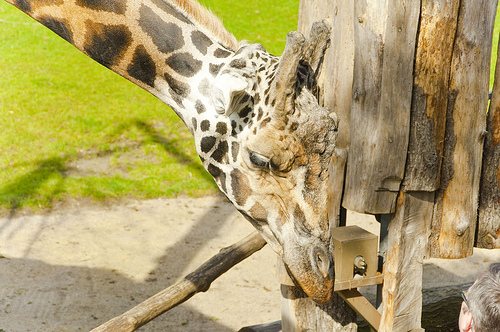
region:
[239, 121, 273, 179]
A giraffe's eye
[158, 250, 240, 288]
A wooden bar in the photo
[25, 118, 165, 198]
Grass on the ground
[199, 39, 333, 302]
A giraffe's neck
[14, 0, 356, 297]
A giraffe in the photo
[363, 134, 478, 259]
Wooden bars in the photo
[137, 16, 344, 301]
A giraffe eating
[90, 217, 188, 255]
A bare ground in the photo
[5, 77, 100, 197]
Grass in the photo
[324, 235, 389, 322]
Metal bar in the photo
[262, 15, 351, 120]
Giraffe ears pointing up.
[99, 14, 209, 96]
Spots on the giraffe's neck.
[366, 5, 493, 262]
Wooden fence beside giraffe's head.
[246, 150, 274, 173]
The eye of a giraffe.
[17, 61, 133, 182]
Grass field in the background.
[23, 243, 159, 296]
Sandy area near the grass.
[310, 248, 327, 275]
Small giraffe nostril.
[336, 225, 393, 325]
Metal bar securing wood.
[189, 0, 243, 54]
Giraffe mane on it's neck.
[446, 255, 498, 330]
Person watching the giraffe.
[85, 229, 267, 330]
A stick under a giraffes mouth.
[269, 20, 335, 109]
Tan horns on top of a giraffes head.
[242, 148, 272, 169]
Dark eye on a giraffes face.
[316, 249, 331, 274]
Nostril on a giraffes face.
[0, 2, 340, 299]
Brown and white giraffe.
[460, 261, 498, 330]
The brown haired head of a man in glasses.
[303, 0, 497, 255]
Five wooden posts to the right of a giraffe head.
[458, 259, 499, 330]
A person in glasses.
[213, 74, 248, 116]
A giraffes right side white ear.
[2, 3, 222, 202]
Bright green grass area under a giraffes neck.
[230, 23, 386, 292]
giraffe head on lock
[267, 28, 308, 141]
right horn on giraffe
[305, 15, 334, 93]
left horn on giraffe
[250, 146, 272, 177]
right eye on giraffe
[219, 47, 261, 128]
right ear on giraffe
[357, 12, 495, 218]
wooden fence by giraffe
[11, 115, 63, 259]
shadow on the ground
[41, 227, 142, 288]
sand on the ground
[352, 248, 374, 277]
metal bolt on lock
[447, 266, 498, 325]
man's head looking at giraffe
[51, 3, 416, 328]
giraffe is bending down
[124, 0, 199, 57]
giraffe has brown spots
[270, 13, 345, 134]
giraffe has brown ears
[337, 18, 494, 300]
wooden platform by giraffe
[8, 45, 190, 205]
grass is next to giraffe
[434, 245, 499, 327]
kid looking at giraffe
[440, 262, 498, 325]
kid has brown hair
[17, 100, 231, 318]
giraffe making shadow on grass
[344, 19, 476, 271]
platform is made of wood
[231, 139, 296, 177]
giraffe has brown eyes